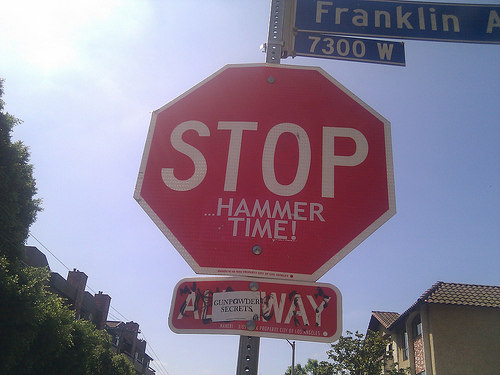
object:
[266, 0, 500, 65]
address sign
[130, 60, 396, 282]
board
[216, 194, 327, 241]
white letters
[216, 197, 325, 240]
words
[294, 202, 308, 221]
letter e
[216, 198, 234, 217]
letter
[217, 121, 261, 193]
letter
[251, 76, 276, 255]
bolts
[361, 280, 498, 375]
buildings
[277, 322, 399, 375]
tree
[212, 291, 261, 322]
sticker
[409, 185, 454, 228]
ground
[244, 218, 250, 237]
letter i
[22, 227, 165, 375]
lines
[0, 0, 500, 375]
sky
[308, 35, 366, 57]
7300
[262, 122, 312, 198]
letter o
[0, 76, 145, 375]
tree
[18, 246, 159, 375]
building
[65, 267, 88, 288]
chimney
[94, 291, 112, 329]
chimney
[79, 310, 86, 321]
window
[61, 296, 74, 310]
window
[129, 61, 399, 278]
sign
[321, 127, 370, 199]
letter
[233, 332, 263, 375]
post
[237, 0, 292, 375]
pole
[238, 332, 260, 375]
holes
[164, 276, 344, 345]
marks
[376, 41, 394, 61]
direction